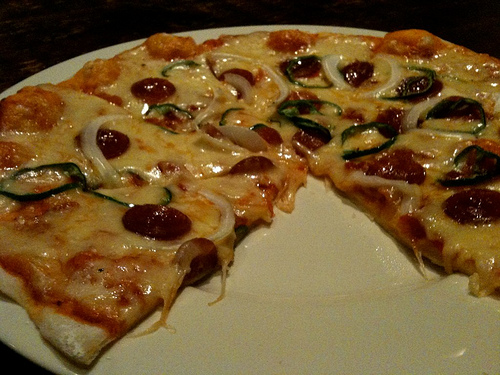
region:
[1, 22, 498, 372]
Pizza on a white plate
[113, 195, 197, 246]
Pepperoni on a pizza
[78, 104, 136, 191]
Onion on pepperoni and cheese pizza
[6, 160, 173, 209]
Green peppers on a pizza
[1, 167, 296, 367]
Pizza slice on a ceramic plate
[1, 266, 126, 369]
Pizza crust with tomato sauce and cheese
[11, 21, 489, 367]
round white ceramic plate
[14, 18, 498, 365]
round white plate with pizza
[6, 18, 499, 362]
very gooey cheese pizza with white crust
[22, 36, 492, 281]
onions and pepperoni topping pizza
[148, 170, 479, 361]
residue of grees on white plate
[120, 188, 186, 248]
round red slice of pepperoni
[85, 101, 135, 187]
sliver of cooked white onion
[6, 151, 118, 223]
string of green pesto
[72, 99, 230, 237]
The slices of onion on the left.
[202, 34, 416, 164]
The slices of onion in the center.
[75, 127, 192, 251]
The pepperonis on the left.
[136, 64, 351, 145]
The pepperonis in the middle.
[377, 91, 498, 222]
The pepperonis on the right.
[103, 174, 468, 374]
The missing slice space in the pizza pie.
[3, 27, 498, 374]
The plate the pizza is on.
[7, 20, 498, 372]
The melted cheese on the pizza.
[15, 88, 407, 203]
The slices of green peppers on the pizza.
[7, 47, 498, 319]
The red sauce on the pizza.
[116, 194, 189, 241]
Topping of a pizza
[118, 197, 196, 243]
Pepperoni on a piece of pizza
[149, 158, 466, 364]
A piece is missing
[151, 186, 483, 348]
A piece of pizza is missing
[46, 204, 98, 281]
Cheese on a pizza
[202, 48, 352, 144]
Toppings on a pizza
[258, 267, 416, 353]
White dinner plate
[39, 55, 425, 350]
The pizza is on a plate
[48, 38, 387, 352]
The pizza is on a white plate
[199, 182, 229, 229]
Onion on a pizza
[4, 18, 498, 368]
pizza over a plate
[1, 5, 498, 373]
plate is color white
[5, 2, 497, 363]
pizza has melted cheese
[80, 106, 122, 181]
slice of white onion